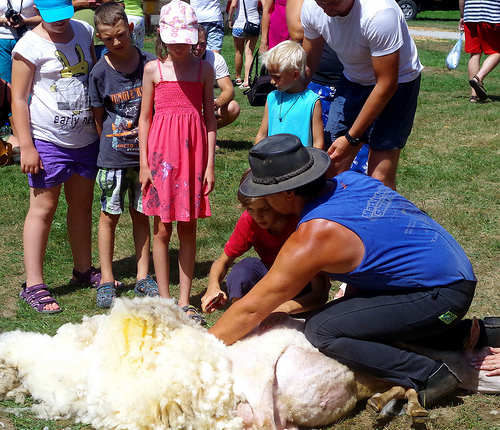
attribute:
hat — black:
[247, 147, 316, 182]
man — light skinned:
[244, 141, 466, 396]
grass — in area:
[443, 94, 474, 141]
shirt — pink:
[17, 45, 96, 137]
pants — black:
[312, 278, 470, 403]